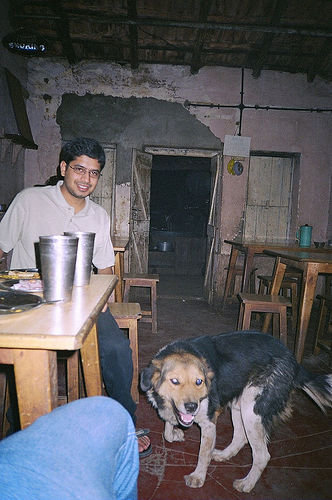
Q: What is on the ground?
A: Dog.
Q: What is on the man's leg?
A: Pants.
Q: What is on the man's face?
A: Glasses.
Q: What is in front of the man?
A: Table.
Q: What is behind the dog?
A: Wooden tables.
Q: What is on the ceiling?
A: Wood cross beam.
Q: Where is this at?
A: Restaurant.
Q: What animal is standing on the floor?
A: Dog.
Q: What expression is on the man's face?
A: Smile.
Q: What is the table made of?
A: Wood.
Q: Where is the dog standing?
A: Floor.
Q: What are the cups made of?
A: Metal.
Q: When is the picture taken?
A: Daytime.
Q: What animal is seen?
A: Dog.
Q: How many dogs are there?
A: 1.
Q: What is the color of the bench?
A: Brown.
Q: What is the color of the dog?
A: Black and brown.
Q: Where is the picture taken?
A: At a neighborhood hangout.